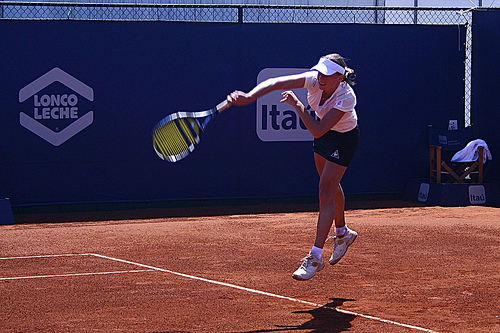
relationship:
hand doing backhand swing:
[226, 90, 248, 107] [149, 73, 305, 165]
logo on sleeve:
[310, 78, 317, 89] [332, 91, 357, 116]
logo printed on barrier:
[16, 65, 93, 145] [1, 19, 498, 221]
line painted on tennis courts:
[92, 252, 184, 278] [0, 215, 498, 325]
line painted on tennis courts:
[0, 266, 140, 280] [0, 215, 498, 325]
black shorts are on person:
[300, 104, 410, 180] [226, 50, 363, 282]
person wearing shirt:
[226, 50, 363, 282] [302, 70, 358, 133]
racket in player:
[151, 89, 241, 163] [229, 50, 358, 281]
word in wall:
[29, 88, 82, 124] [2, 17, 498, 220]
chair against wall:
[418, 122, 493, 209] [2, 17, 498, 220]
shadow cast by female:
[257, 294, 369, 326] [210, 43, 362, 295]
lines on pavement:
[50, 245, 215, 277] [1, 203, 496, 328]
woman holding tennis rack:
[226, 53, 361, 281] [148, 99, 232, 164]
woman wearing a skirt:
[231, 43, 388, 293] [297, 122, 367, 175]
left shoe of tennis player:
[291, 250, 325, 280] [152, 53, 359, 280]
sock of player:
[305, 242, 325, 266] [257, 16, 373, 300]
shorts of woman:
[316, 132, 364, 164] [271, 37, 383, 226]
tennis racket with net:
[149, 95, 232, 164] [155, 118, 195, 155]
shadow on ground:
[302, 300, 352, 332] [332, 270, 377, 292]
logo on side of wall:
[12, 57, 102, 143] [15, 37, 143, 216]